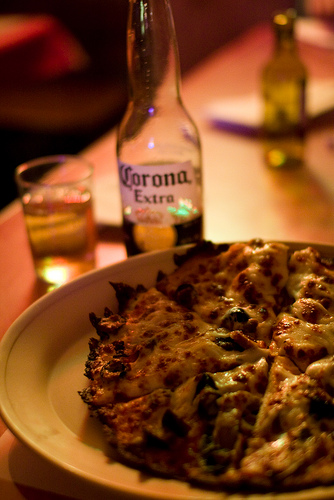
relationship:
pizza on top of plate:
[77, 241, 333, 490] [0, 240, 333, 499]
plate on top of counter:
[0, 240, 333, 499] [0, 2, 332, 497]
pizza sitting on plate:
[77, 241, 333, 490] [0, 240, 333, 499]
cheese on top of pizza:
[95, 247, 333, 480] [77, 241, 333, 490]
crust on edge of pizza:
[77, 282, 154, 408] [77, 241, 333, 490]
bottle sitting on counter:
[115, 1, 205, 260] [0, 2, 332, 497]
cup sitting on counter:
[15, 154, 97, 287] [0, 2, 332, 497]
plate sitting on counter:
[0, 240, 333, 499] [0, 2, 332, 497]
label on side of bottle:
[115, 159, 202, 258] [115, 1, 205, 260]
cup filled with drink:
[15, 154, 97, 287] [21, 187, 94, 287]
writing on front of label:
[117, 164, 192, 203] [115, 159, 202, 258]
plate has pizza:
[0, 240, 333, 499] [77, 241, 333, 490]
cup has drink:
[15, 154, 97, 287] [21, 187, 94, 287]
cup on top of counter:
[15, 154, 97, 287] [0, 2, 332, 497]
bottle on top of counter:
[115, 1, 205, 260] [0, 2, 332, 497]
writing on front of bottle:
[117, 164, 192, 203] [115, 1, 205, 260]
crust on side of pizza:
[77, 282, 154, 408] [77, 241, 333, 490]